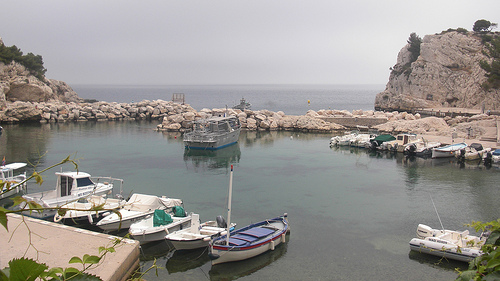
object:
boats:
[0, 160, 31, 198]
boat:
[182, 113, 243, 151]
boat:
[209, 211, 290, 265]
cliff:
[373, 27, 500, 112]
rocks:
[98, 105, 114, 112]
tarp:
[152, 208, 173, 226]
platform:
[0, 212, 145, 281]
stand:
[171, 92, 186, 105]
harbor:
[0, 102, 500, 281]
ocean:
[71, 83, 380, 114]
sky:
[0, 0, 500, 84]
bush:
[0, 39, 46, 85]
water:
[0, 122, 500, 281]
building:
[0, 212, 152, 281]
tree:
[470, 18, 494, 32]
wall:
[0, 59, 77, 122]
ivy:
[0, 255, 109, 281]